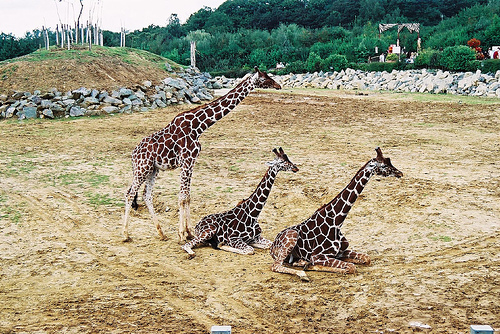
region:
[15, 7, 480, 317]
animals in a nature park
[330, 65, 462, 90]
stone retaining wall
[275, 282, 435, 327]
loose dirt in the animals' pen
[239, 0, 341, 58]
park's thick vegetation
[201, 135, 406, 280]
two giraffe's sitting in the dirt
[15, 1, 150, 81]
spindly trees atop a mound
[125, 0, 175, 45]
glimpse of the sky and trees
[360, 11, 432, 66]
structure a the side of the animal's area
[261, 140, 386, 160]
two sets of ossicones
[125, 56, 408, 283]
three giraffe's facing the same direction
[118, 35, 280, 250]
this is a giraffe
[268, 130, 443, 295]
giraffe is laying down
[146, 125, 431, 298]
two giraffes laying down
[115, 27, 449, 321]
three giraffes facing the same direction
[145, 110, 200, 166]
brown spots on the giraffe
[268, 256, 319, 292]
leg of the giraffe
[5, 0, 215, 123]
rocks around a hill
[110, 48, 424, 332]
giraffes laying on dirt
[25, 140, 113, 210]
small patch of grass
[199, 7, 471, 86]
lush trees on the side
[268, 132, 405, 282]
The giraffe is laying on the ground.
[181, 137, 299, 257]
The giraffe is laying on the ground.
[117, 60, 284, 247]
The giraffe is standing.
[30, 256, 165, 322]
The ground is brown in color.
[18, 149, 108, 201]
The is very little grass on the ground.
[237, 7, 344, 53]
The trees are green.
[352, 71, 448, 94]
The rocks are white.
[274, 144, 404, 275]
The giraffe is brown and white.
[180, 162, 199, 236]
The giraffes legs are long.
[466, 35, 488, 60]
The tree in the background is red.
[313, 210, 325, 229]
The spot is brown.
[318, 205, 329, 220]
The spot is brown.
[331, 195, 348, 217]
The spot is brown.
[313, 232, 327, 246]
The spot is brown.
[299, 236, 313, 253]
The spot is brown.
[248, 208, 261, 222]
The spot is brown.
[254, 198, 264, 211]
The spot is brown.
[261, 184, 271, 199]
The spot is brown.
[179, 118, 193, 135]
The spot is brown.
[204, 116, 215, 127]
The spot is brown.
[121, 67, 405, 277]
three giraffes in the dirt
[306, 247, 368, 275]
the folded legs of the giraffe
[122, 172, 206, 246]
the standing legs of the giraffe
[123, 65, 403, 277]
giraffes in a row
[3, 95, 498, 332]
an expanse of tan dirt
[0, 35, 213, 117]
a small grassy mound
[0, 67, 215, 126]
rocks around the mound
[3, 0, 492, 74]
tall green trees around the clearing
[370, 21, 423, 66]
a small structure by the trees